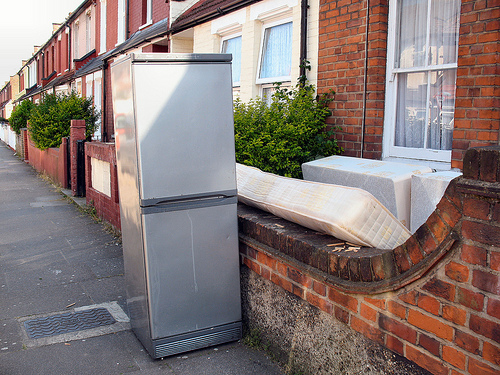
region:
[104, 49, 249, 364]
Old stainless steel appliance on the sidewalk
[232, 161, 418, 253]
Old mattress beside the appliance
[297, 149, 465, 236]
Two box springs beside the mattress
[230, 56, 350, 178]
Green plant beside the appliance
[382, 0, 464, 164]
Window trimmed in wood behind the mattress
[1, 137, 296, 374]
Sidewalk in front of the buildings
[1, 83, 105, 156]
Green plants to the left of the appliance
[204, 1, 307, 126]
Two white wooden windows behind the appliance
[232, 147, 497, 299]
Arched stone planter area that the mattress is in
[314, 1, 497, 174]
Red bricks behind the mattress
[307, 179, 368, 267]
the mattress is leaning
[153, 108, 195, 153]
the refrigerator is gray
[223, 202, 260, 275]
the refrigerator is by the wall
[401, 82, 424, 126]
the curtains are closed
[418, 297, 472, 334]
the bricks are brown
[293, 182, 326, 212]
the mattress is white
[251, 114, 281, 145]
the bush is green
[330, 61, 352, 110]
the building is made os bricks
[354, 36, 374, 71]
the pipe is gray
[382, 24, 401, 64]
the frame is white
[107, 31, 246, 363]
A refrigerator on the street.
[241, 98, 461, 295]
A mattress and box springs.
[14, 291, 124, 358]
A metal grate on the street.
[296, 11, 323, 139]
A black pipe going up the building.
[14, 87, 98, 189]
A bush in an enclosure.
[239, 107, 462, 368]
A mattress outside a window.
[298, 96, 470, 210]
Box springs outside a window.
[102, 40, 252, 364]
A stainless steel refrigerator.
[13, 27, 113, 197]
A row of brick houses.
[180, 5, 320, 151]
A white brick house.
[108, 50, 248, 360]
old silver refrigerator sitting outside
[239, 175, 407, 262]
mattress sitting outside near a refrigerator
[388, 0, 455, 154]
white curtains hanging in the window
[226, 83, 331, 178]
green bushes behind the fridge and mattress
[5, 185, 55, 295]
black pavement outside on the street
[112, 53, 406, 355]
refrigerator and mattresses sitting outside of a building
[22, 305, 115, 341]
metal plate on the street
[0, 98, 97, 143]
green bushes in the background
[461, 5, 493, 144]
bricks around the window on the building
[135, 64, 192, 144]
sunny corner on the otherwise shaded refrigerator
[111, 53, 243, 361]
silver freezer on the sidewalk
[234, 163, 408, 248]
mattress behind brick wall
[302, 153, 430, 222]
mattress behind brick wall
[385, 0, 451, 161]
window behind matresses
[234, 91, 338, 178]
green bush behind mattresses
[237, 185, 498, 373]
bricks on the wall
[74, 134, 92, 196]
black gate behind freezer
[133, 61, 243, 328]
freezer has two doors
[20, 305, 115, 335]
utility door in sidewalk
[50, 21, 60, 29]
chimney on house